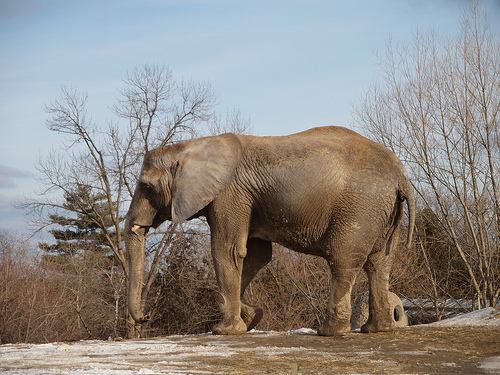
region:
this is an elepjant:
[65, 65, 451, 361]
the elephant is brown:
[97, 86, 459, 353]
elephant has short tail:
[376, 123, 437, 274]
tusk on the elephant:
[122, 208, 156, 247]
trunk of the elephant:
[112, 193, 170, 333]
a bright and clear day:
[5, 28, 477, 363]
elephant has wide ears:
[140, 131, 245, 228]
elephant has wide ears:
[163, 128, 265, 250]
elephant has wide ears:
[149, 136, 264, 237]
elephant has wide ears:
[146, 125, 262, 239]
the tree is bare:
[374, 37, 488, 314]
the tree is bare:
[376, 39, 497, 287]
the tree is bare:
[376, 29, 498, 313]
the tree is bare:
[380, 42, 494, 294]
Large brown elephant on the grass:
[112, 109, 421, 349]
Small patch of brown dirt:
[20, 332, 70, 363]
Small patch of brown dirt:
[81, 331, 132, 366]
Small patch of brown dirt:
[140, 321, 174, 360]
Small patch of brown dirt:
[172, 325, 238, 364]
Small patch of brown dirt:
[248, 321, 307, 351]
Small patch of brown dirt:
[307, 316, 404, 373]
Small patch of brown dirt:
[405, 316, 445, 345]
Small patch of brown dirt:
[455, 330, 485, 359]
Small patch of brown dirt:
[170, 349, 191, 371]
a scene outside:
[2, 47, 498, 372]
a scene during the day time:
[4, 41, 499, 373]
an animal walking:
[96, 118, 431, 347]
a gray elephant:
[97, 120, 429, 352]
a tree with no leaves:
[357, 40, 497, 304]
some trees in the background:
[4, 49, 497, 325]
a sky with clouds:
[5, 4, 494, 249]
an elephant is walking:
[124, 126, 416, 334]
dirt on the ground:
[1, 326, 498, 374]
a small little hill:
[409, 307, 498, 326]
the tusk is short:
[130, 224, 141, 233]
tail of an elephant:
[405, 196, 416, 250]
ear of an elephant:
[171, 133, 241, 222]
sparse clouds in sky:
[0, 0, 499, 260]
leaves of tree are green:
[41, 184, 125, 277]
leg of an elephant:
[210, 201, 249, 333]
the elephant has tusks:
[119, 202, 161, 246]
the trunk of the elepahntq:
[98, 198, 191, 343]